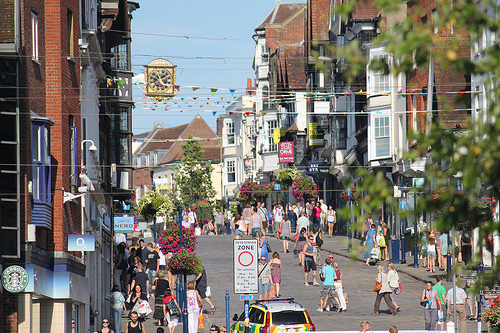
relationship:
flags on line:
[205, 85, 250, 104] [310, 103, 441, 124]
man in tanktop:
[295, 233, 320, 292] [301, 242, 320, 263]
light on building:
[80, 134, 104, 175] [4, 9, 139, 320]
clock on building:
[141, 53, 179, 102] [4, 9, 139, 320]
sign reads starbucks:
[2, 256, 30, 304] [4, 265, 29, 296]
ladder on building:
[2, 54, 29, 259] [4, 9, 139, 320]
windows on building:
[367, 41, 401, 159] [261, 10, 472, 219]